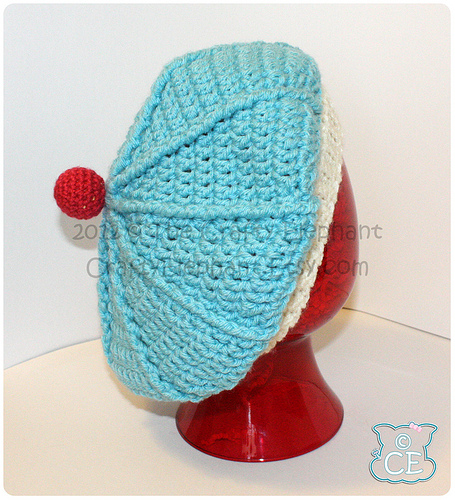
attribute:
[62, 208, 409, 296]
watermark — elephant watermark, crafty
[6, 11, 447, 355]
background — white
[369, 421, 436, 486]
logo — outlined, green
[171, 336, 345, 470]
base — red, plastic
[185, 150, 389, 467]
object — red, plastic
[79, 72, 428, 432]
mannequin — see through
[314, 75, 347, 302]
trim — white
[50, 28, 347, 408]
hat — blue, whie, white, handmade, crocheted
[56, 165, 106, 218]
ball — red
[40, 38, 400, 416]
hat — blue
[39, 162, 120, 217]
poof — red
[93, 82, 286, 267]
thread — green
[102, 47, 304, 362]
hat — blue, knitted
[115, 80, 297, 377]
hat — blue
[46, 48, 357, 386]
hat — handmade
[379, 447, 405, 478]
letter — white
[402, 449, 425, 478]
letter — white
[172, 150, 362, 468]
mannequin — red